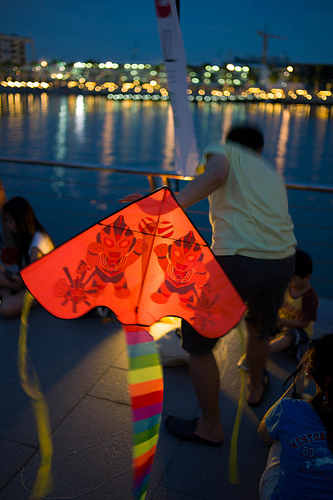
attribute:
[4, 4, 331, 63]
sky — lit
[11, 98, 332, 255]
water — calm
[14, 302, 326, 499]
ground — paved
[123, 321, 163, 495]
tail — rainbow, colorful, multi-color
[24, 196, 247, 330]
kite — red, orange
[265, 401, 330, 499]
shirt — blue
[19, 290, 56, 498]
tail — yellow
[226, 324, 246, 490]
tail — yellow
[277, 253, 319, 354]
boy — sitting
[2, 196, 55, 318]
girl — sitting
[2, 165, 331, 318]
fence — metal, steel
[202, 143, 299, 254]
shirt — white, yellow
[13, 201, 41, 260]
hair — long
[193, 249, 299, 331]
shorts — dark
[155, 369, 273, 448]
sandals — pull-on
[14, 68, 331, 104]
lights — shining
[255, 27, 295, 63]
crane — silhouette